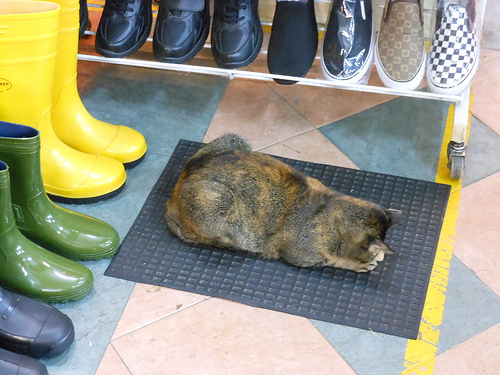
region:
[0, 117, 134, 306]
green plastic boots on ground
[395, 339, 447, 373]
yellow line painted on tile floor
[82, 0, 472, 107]
row of shoes on white rack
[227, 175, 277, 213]
fur on back of cat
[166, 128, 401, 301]
cat sleeping on black mat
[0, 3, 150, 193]
plastic yellow boots on floor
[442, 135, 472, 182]
wheel on white cart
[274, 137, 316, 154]
small scratch in floor tile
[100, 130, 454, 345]
A cat is sleeping on a mat.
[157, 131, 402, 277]
The cat is light brown and dark brown.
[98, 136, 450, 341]
The mat is black.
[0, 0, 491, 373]
Some shoes are around the cat.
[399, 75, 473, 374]
A yellow line is on the ground.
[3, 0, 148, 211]
A pair of yellow rain boots.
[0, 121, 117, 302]
A pair of green rain boots.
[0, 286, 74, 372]
A pair of black boots.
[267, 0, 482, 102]
The pairs of shoes are mismatched.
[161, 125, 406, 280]
The cat is sleeping.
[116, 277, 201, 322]
red tile on floor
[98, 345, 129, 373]
red tile on floor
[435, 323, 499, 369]
red tile on floor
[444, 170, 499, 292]
red tile on floor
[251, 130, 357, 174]
red tile on floor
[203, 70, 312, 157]
red tile on floor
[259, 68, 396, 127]
red tile on floor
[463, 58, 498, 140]
red tile on floor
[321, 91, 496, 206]
black tile on floor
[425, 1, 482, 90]
shoe on a shoe rack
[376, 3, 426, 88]
shoe on a shoe rack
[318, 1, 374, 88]
shoe on a shoe rack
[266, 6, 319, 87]
shoe on a shoe rack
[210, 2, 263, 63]
shoe on a shoe rack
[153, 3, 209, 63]
shoe on a shoe rack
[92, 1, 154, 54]
shoe on a shoe rack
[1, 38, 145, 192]
boots on the floor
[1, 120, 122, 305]
boots on the floor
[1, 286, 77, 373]
boots on the floor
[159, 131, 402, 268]
black and orange calico cat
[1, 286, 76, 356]
tow of Black boot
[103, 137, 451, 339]
black mat on the floor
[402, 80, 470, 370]
yellow stripe on the floor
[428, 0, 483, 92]
black and white checkered shoe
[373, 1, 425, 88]
brown checkered shoe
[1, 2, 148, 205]
yellow rain boots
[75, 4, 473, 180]
white rack for shoes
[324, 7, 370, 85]
black shiny shoe with white trim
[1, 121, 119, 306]
olive green rain boots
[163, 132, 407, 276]
brown black and grey cat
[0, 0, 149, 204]
yellow rubber boots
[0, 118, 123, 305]
green rubber boots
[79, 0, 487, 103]
white metal rack with shoes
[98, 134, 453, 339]
cat on black rubber floor mat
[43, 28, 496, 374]
pink and blue tiled floor